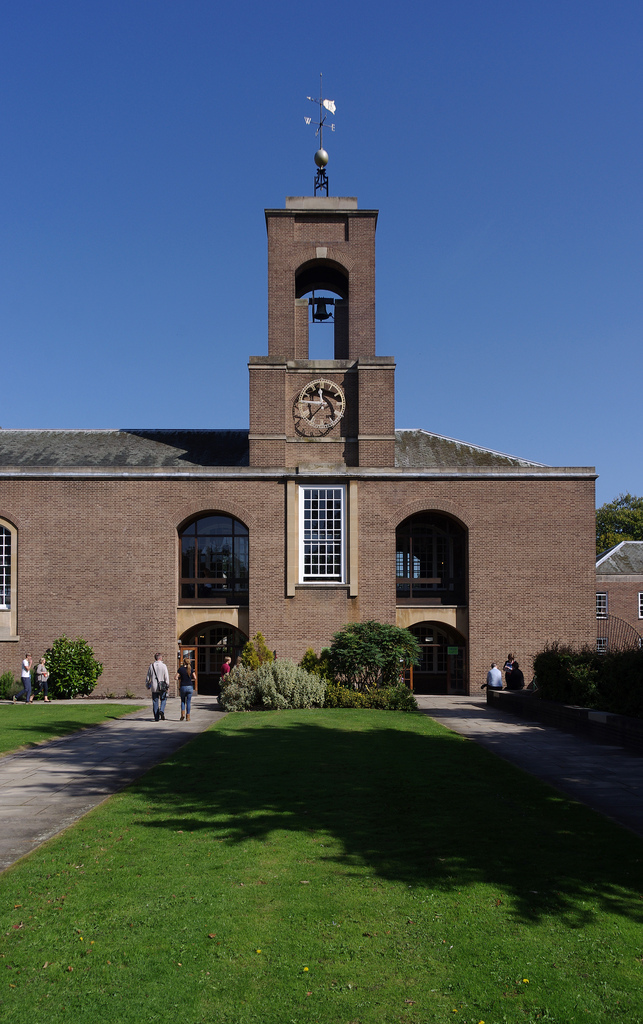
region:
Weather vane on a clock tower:
[300, 68, 340, 191]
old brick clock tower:
[251, 198, 380, 463]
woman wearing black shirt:
[178, 660, 200, 719]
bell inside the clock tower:
[311, 294, 335, 323]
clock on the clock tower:
[297, 379, 347, 434]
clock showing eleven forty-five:
[295, 377, 348, 432]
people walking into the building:
[20, 652, 239, 722]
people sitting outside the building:
[484, 650, 526, 698]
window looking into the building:
[300, 488, 346, 587]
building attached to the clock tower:
[2, 429, 601, 698]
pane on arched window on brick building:
[180, 516, 200, 533]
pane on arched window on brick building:
[194, 511, 236, 535]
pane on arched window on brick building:
[233, 514, 250, 535]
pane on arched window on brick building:
[179, 533, 198, 580]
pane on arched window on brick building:
[195, 534, 236, 577]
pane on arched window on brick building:
[232, 532, 249, 581]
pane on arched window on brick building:
[177, 579, 197, 601]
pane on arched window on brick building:
[195, 576, 234, 601]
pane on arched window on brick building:
[228, 579, 248, 596]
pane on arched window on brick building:
[397, 533, 414, 581]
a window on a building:
[2, 516, 6, 625]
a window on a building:
[188, 533, 234, 588]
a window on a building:
[235, 542, 256, 598]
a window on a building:
[201, 507, 231, 534]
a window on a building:
[230, 516, 250, 535]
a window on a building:
[176, 577, 193, 606]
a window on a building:
[196, 575, 224, 599]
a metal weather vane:
[297, 63, 346, 147]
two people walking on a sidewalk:
[140, 649, 196, 727]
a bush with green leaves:
[337, 616, 421, 673]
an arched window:
[173, 498, 251, 605]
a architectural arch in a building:
[400, 618, 473, 696]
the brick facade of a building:
[1, 475, 596, 698]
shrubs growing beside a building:
[226, 617, 422, 716]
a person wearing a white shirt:
[18, 654, 31, 676]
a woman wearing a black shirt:
[173, 659, 199, 682]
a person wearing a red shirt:
[225, 657, 233, 671]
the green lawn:
[4, 699, 641, 1018]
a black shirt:
[175, 664, 197, 686]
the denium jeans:
[21, 676, 196, 716]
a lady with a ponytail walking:
[174, 650, 199, 721]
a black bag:
[147, 661, 171, 697]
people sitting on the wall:
[478, 657, 529, 698]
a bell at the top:
[308, 293, 334, 326]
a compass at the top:
[299, 78, 344, 143]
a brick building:
[3, 77, 642, 696]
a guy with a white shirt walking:
[18, 656, 31, 675]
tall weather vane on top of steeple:
[291, 85, 354, 199]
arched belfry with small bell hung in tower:
[287, 250, 358, 361]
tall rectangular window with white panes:
[294, 479, 353, 589]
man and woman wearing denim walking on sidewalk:
[139, 647, 204, 722]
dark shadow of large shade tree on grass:
[7, 713, 640, 933]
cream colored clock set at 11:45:
[290, 374, 354, 441]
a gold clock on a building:
[290, 366, 352, 437]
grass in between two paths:
[6, 709, 626, 1002]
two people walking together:
[126, 636, 219, 737]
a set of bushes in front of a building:
[215, 608, 431, 709]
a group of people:
[463, 624, 555, 705]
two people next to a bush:
[11, 632, 119, 705]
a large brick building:
[8, 190, 626, 691]